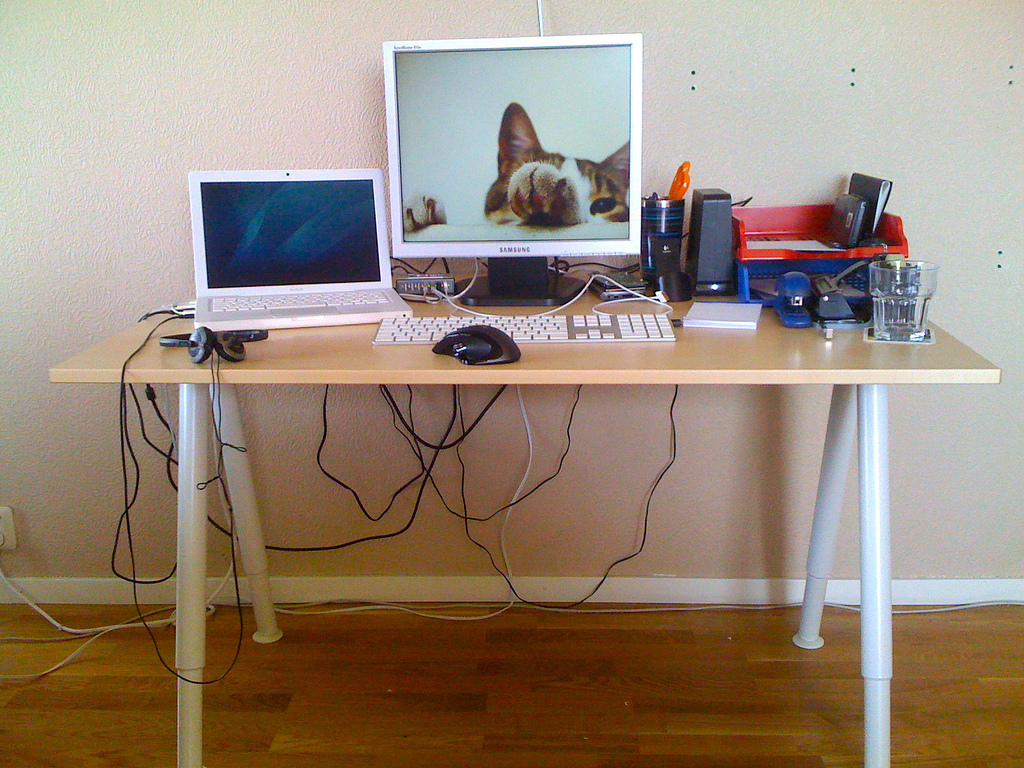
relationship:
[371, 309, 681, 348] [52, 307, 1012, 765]
keyboard on desk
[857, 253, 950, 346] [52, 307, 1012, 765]
glass on desk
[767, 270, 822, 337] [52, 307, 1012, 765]
stapler on desk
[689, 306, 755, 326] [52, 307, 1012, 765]
paper on desk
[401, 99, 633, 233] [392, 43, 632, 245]
cat in picture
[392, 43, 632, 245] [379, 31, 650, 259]
picture on monitor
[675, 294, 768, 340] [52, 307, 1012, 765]
paper pad sitting on desk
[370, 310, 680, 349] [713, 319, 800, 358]
keyboard on a desk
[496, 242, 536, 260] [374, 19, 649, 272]
logo on monitor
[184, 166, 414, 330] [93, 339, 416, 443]
laptop sitting on desk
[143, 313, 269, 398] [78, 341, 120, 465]
headphones laying on top of desk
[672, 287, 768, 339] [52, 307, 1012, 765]
pad on desk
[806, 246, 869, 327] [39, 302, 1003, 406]
hole punch on desk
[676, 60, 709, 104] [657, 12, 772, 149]
holes in wall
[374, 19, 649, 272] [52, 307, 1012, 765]
monitor on desk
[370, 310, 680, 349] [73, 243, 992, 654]
keyboard on desk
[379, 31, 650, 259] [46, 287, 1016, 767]
monitor on desk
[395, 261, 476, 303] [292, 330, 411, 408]
modem on top of desk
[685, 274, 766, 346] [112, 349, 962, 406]
paper on top of desk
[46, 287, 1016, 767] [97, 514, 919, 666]
desk with white legs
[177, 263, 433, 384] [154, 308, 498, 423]
laptop on a desk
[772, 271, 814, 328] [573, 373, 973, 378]
stapler on a desk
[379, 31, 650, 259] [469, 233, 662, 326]
monitor on computer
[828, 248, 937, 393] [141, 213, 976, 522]
empty glass sitting on top of desk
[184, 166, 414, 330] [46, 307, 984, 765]
laptop sitting on top of table